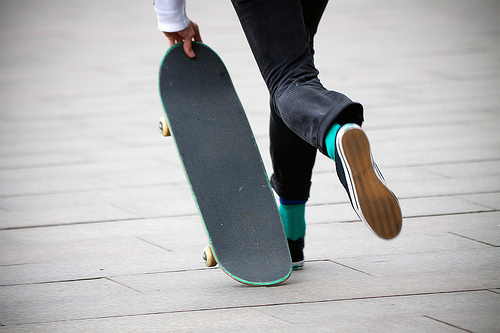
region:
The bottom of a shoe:
[336, 122, 408, 239]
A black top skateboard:
[153, 41, 295, 283]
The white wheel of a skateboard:
[201, 242, 221, 268]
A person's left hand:
[162, 20, 203, 56]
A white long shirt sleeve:
[152, 0, 194, 32]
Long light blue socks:
[280, 196, 307, 243]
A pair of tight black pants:
[232, 1, 362, 199]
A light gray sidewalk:
[0, 52, 497, 332]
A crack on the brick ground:
[20, 275, 111, 287]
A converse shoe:
[332, 124, 406, 244]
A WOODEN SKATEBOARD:
[155, 37, 295, 287]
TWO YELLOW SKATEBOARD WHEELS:
[157, 115, 219, 275]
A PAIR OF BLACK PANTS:
[229, 0, 367, 207]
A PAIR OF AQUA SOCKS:
[274, 116, 348, 243]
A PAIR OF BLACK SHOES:
[286, 119, 404, 271]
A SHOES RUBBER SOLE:
[338, 126, 405, 242]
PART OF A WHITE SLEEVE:
[151, 2, 196, 34]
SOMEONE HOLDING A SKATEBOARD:
[150, 0, 405, 290]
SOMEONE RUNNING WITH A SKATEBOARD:
[151, 0, 407, 287]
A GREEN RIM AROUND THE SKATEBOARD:
[156, 39, 296, 290]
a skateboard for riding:
[107, 12, 415, 269]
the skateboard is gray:
[133, 37, 305, 306]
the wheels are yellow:
[144, 107, 221, 274]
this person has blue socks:
[262, 114, 376, 246]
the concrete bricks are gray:
[47, 100, 468, 310]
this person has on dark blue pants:
[227, 7, 371, 199]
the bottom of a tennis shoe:
[315, 129, 425, 257]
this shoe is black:
[285, 233, 325, 279]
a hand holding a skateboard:
[142, 8, 228, 74]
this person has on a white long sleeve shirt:
[148, 3, 215, 66]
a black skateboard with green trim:
[155, 44, 290, 286]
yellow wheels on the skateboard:
[158, 117, 215, 264]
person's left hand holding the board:
[154, 0, 201, 55]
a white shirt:
[153, 0, 187, 31]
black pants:
[232, 1, 364, 199]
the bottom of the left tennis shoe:
[336, 127, 403, 241]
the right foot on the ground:
[277, 204, 304, 270]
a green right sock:
[279, 205, 303, 237]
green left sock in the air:
[323, 121, 338, 156]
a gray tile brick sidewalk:
[5, 10, 490, 332]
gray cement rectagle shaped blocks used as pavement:
[423, 0, 493, 330]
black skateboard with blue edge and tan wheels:
[152, 35, 294, 286]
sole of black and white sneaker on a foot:
[332, 122, 406, 246]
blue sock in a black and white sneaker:
[271, 198, 311, 248]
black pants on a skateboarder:
[220, 0, 365, 200]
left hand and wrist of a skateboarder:
[145, 0, 204, 60]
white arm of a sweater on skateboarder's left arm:
[145, 0, 199, 37]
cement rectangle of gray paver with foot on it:
[102, 256, 377, 297]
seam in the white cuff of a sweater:
[173, 5, 194, 30]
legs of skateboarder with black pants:
[219, 0, 424, 279]